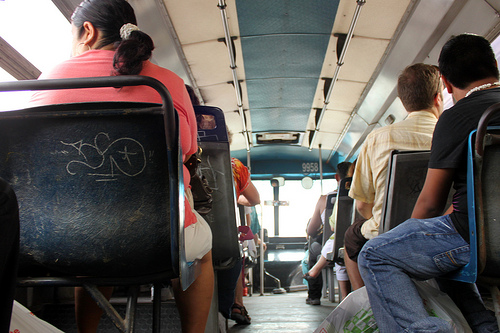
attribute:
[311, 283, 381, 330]
shopping bag — large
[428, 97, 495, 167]
shirt — black 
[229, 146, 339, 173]
trim — blue, painted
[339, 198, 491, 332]
jeans — blue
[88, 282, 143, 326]
legs — metallic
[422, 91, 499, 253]
t-shirt — black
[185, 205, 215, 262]
shorts — white 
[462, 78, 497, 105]
necklace — white 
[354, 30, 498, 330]
man — shell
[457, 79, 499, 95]
shell necklace — white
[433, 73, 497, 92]
necklace — white 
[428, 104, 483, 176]
t-shirt — black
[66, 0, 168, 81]
hair — long, black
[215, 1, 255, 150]
bar — metallic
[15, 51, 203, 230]
shirt — red 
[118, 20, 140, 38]
hair band — white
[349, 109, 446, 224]
shirt — white